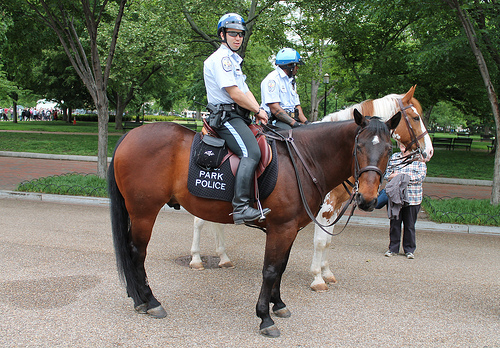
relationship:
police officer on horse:
[209, 13, 275, 228] [103, 105, 404, 340]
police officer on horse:
[200, 13, 273, 227] [103, 105, 404, 340]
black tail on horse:
[104, 128, 149, 295] [103, 105, 404, 340]